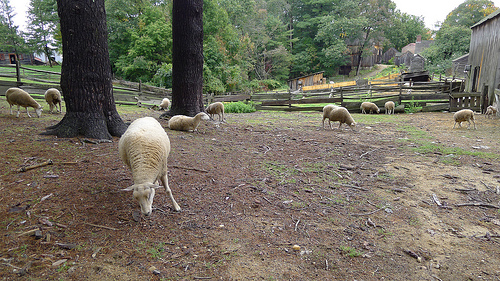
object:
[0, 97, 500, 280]
ground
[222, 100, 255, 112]
grass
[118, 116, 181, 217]
sheep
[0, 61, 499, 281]
dirt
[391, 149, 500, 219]
pen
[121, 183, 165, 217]
head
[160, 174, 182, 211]
leg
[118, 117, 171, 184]
wool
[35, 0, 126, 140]
tree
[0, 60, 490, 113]
fence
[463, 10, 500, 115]
barn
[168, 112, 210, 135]
sheep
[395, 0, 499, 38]
sky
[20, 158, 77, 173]
stick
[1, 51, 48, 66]
house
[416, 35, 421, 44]
chimney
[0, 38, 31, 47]
roof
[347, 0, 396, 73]
tree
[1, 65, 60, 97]
hill